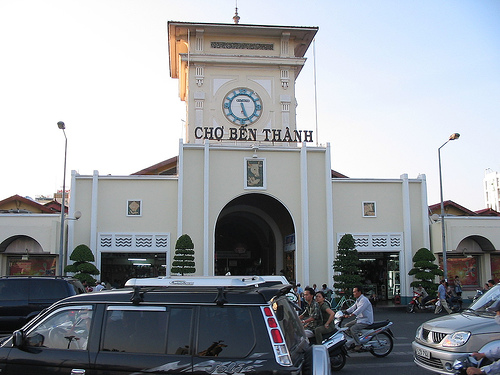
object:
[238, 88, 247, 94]
number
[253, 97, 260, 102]
number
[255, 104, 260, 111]
number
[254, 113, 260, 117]
number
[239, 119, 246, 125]
number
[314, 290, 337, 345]
person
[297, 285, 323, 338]
person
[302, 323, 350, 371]
bike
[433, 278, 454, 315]
man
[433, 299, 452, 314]
pants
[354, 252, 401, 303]
entrance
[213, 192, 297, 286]
entrance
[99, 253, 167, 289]
entrance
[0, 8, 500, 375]
market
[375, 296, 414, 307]
sidewalk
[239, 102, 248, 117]
hands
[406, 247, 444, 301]
topiaries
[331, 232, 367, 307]
topiaries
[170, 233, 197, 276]
topiaries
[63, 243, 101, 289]
topiaries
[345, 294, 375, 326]
shirt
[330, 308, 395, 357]
motorbike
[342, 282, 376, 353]
man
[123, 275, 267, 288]
rack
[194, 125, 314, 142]
writing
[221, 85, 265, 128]
clock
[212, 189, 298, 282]
arch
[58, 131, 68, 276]
light pole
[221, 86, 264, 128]
clock face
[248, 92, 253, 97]
number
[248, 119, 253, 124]
number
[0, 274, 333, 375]
black suv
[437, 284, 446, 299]
shirt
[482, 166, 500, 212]
building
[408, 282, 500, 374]
gray vehicle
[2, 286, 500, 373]
foreground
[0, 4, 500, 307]
building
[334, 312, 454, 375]
road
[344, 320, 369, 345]
pants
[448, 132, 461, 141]
light